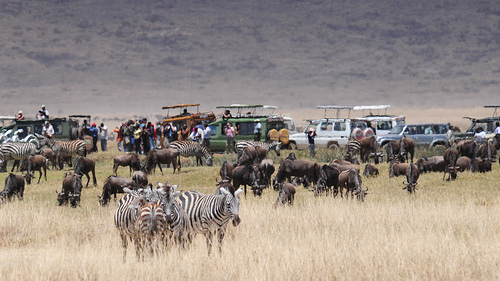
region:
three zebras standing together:
[108, 182, 244, 259]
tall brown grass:
[6, 195, 494, 279]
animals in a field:
[0, 138, 499, 279]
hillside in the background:
[0, 0, 499, 118]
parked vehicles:
[1, 110, 499, 147]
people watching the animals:
[8, 105, 315, 153]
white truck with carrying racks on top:
[286, 102, 374, 154]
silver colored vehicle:
[378, 121, 458, 149]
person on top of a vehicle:
[1, 103, 78, 143]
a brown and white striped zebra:
[49, 138, 88, 160]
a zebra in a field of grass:
[172, 177, 249, 259]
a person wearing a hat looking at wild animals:
[302, 125, 318, 157]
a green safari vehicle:
[204, 96, 286, 158]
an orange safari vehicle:
[135, 94, 210, 162]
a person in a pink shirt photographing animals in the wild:
[221, 120, 243, 158]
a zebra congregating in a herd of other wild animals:
[0, 134, 45, 173]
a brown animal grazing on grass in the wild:
[0, 170, 27, 212]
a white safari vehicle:
[290, 97, 378, 160]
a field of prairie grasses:
[0, 197, 498, 279]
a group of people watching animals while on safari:
[2, 81, 499, 273]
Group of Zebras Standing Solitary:
[115, 192, 261, 255]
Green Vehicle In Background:
[210, 110, 277, 150]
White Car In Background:
[290, 103, 371, 152]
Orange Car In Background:
[144, 97, 209, 145]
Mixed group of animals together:
[3, 134, 104, 179]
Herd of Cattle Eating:
[210, 153, 375, 203]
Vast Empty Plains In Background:
[1, 0, 497, 104]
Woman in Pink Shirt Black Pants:
[217, 124, 240, 150]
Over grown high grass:
[254, 203, 495, 280]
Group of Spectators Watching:
[115, 119, 180, 155]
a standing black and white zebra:
[179, 184, 244, 254]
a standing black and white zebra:
[116, 187, 135, 257]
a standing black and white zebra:
[1, 140, 34, 170]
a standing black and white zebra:
[161, 184, 191, 250]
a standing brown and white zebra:
[131, 197, 165, 261]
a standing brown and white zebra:
[46, 138, 86, 163]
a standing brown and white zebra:
[167, 138, 214, 168]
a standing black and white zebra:
[231, 138, 282, 161]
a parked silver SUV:
[289, 116, 369, 153]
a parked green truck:
[194, 118, 288, 153]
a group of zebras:
[105, 175, 263, 267]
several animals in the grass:
[4, 123, 493, 278]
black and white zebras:
[101, 184, 258, 255]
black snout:
[232, 219, 242, 229]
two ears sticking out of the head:
[218, 182, 248, 199]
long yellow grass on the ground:
[4, 145, 499, 280]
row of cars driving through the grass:
[19, 95, 499, 168]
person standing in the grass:
[302, 118, 323, 156]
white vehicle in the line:
[287, 107, 367, 158]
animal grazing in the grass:
[93, 170, 145, 210]